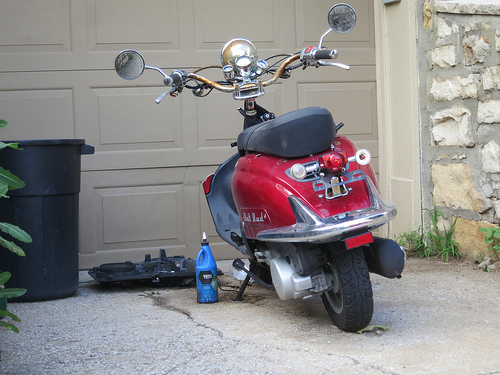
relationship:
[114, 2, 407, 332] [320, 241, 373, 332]
motorcycle has a tire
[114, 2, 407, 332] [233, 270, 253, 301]
motorcycle has a kickstand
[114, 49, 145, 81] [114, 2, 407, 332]
left rearview mirror on motorcycle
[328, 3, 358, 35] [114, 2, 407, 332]
right rearview mirro on motorcycle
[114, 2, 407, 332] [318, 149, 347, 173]
motorcycle has a taillight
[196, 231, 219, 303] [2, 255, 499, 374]
bottle on ground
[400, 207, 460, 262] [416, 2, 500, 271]
grass in front of wall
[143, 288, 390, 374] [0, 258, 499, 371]
crack in concrete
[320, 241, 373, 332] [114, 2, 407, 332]
tire on motorcycle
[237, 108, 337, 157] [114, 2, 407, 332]
seat on motorcycle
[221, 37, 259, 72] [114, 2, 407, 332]
head lamp on motorcycle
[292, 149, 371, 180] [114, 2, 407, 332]
break lights on motorcycle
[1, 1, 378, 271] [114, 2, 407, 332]
garage door in front of motorcycle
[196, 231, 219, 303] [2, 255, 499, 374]
bottle sitting on ground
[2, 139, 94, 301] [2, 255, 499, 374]
trash can sitting on ground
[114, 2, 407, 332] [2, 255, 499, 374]
motorcycle sitting on ground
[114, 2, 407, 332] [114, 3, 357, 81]
motorcycle has two rearview mirrors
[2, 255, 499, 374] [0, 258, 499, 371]
ground made of concrete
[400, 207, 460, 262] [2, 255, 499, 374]
grass growing on ground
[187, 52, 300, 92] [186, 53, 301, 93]
rust on handles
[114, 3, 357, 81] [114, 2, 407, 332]
rearview mirrors on motorcycle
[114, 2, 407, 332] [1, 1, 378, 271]
motorcycle parked by garage door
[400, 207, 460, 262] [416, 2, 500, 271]
grass growing by wall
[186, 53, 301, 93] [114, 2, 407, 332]
handles on motorcycle